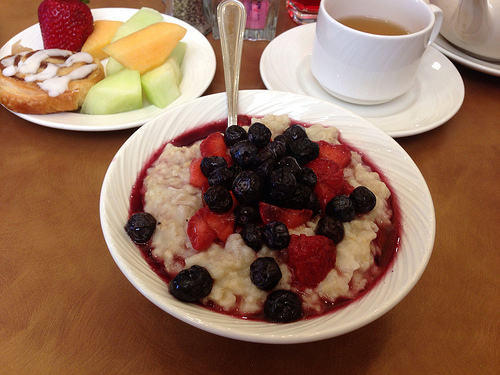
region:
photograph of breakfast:
[12, 6, 492, 348]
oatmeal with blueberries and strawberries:
[131, 102, 418, 326]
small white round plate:
[9, 3, 202, 125]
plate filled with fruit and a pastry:
[7, 0, 201, 122]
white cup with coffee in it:
[317, 2, 439, 86]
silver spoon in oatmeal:
[207, 0, 260, 137]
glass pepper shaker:
[167, 0, 214, 37]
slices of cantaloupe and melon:
[92, 5, 172, 109]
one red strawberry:
[34, 0, 100, 55]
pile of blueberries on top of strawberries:
[202, 125, 315, 216]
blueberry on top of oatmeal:
[195, 155, 223, 180]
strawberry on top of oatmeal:
[288, 227, 341, 291]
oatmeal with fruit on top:
[151, 110, 378, 306]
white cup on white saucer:
[262, 0, 469, 135]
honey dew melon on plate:
[81, 70, 148, 112]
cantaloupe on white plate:
[103, 19, 190, 71]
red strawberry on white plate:
[34, 2, 94, 57]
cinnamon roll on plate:
[1, 40, 88, 119]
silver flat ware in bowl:
[213, 0, 253, 135]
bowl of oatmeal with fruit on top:
[97, 5, 437, 344]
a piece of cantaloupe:
[100, 20, 189, 72]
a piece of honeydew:
[82, 67, 146, 113]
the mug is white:
[311, 0, 445, 107]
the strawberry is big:
[35, 0, 94, 53]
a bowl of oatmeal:
[98, 85, 438, 340]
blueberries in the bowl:
[127, 117, 379, 319]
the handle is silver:
[211, 2, 249, 134]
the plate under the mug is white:
[257, 17, 467, 144]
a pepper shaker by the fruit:
[161, 0, 216, 37]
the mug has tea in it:
[305, 0, 445, 101]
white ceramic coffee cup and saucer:
[261, 1, 464, 138]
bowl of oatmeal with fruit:
[99, 88, 436, 344]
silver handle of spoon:
[216, 0, 248, 126]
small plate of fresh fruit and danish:
[2, 0, 218, 132]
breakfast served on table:
[1, 0, 497, 373]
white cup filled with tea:
[315, 0, 441, 103]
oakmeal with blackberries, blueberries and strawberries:
[100, 89, 435, 344]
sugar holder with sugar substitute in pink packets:
[210, 0, 275, 40]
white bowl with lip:
[101, 88, 436, 343]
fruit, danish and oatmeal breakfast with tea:
[0, 0, 468, 347]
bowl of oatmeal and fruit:
[99, 86, 455, 343]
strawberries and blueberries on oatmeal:
[193, 124, 373, 280]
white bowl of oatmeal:
[96, 88, 441, 345]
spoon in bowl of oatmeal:
[216, 0, 247, 127]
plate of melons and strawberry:
[5, 5, 219, 132]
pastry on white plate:
[1, 46, 104, 113]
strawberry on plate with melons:
[36, 0, 94, 58]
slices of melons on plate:
[86, 5, 185, 112]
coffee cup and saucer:
[259, 1, 466, 138]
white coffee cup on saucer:
[308, 0, 445, 107]